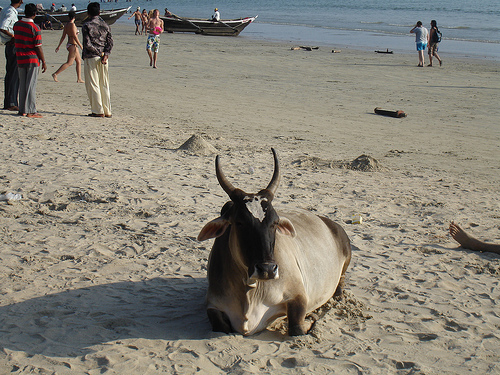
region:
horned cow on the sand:
[199, 153, 352, 335]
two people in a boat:
[164, 3, 256, 36]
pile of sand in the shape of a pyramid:
[177, 132, 219, 155]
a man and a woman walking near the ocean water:
[412, 18, 440, 68]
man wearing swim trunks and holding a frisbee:
[145, 8, 162, 65]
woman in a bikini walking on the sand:
[51, 9, 82, 86]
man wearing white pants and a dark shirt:
[77, 3, 114, 115]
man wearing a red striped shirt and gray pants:
[13, 4, 47, 117]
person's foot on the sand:
[445, 221, 498, 256]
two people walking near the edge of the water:
[408, 17, 448, 72]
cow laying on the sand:
[201, 150, 358, 336]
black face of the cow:
[228, 195, 285, 280]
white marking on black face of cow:
[245, 195, 266, 221]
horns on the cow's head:
[207, 145, 282, 195]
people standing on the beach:
[2, 2, 118, 118]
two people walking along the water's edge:
[410, 13, 447, 66]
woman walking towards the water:
[56, 8, 82, 74]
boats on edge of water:
[34, 1, 256, 38]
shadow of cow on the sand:
[2, 272, 216, 358]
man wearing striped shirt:
[8, 5, 50, 112]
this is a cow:
[167, 90, 385, 357]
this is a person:
[422, 9, 456, 83]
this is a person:
[394, 5, 443, 85]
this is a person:
[135, 8, 172, 63]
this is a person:
[69, 0, 126, 117]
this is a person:
[12, 4, 57, 121]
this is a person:
[3, 4, 43, 103]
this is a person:
[52, 10, 99, 106]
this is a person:
[131, 4, 152, 39]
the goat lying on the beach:
[197, 147, 351, 336]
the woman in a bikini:
[50, 12, 85, 84]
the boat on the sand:
[158, 14, 257, 36]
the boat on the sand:
[4, 5, 133, 27]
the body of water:
[1, 0, 498, 42]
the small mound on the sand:
[180, 133, 222, 154]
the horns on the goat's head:
[215, 147, 281, 201]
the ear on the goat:
[275, 217, 295, 238]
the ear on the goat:
[196, 215, 230, 241]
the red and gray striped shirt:
[12, 17, 41, 67]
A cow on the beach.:
[195, 156, 362, 336]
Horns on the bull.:
[199, 120, 289, 192]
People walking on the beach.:
[400, 10, 466, 73]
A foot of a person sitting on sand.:
[443, 208, 492, 251]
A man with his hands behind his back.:
[79, 21, 128, 71]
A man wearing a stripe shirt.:
[9, 23, 46, 68]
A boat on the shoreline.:
[156, 11, 256, 43]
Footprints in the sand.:
[18, 179, 157, 275]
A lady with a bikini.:
[55, 5, 87, 77]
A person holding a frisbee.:
[137, 7, 169, 58]